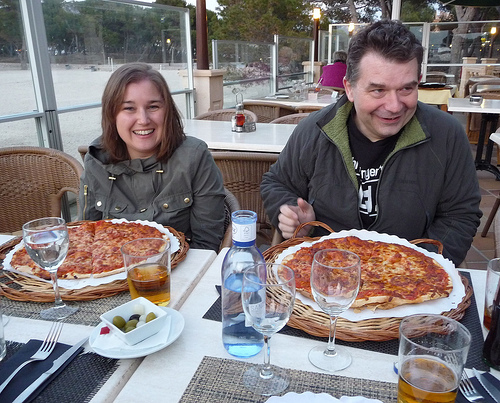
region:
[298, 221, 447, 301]
large pizza in basket tray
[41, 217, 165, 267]
large pizza in basket tray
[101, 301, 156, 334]
olives in square tray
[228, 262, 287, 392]
clear water glass on table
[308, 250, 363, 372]
clear water glass on table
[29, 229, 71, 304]
clear water glass on table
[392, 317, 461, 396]
glass of beer on table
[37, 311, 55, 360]
fork on placemat on table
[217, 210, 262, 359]
bottle of water on table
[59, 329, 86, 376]
knife laying on table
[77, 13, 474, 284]
coouple sitting at table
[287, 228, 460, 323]
pizza on white plate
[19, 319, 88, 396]
silver utensils on table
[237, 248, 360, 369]
two empty wine glasses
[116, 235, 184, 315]
glass half full of beer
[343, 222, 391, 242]
edge of white plate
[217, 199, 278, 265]
bottle neck with no cap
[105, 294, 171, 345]
olives in white dish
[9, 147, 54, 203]
back of wicker chair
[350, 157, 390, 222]
white design on black shirt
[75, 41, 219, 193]
girl looking at the camera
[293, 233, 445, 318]
pizza under the man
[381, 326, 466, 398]
glass on the table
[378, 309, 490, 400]
half full glass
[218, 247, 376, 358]
two wine glasses on the table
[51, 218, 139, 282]
pizza in front of woman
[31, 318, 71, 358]
fork on the table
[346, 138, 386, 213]
black and white shirt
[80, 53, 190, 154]
brown hair on girl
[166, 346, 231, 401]
placemat on table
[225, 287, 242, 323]
part of a bottle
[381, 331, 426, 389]
part of a glass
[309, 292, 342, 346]
part of a stand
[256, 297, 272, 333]
part of a glass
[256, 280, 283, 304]
edge of a glas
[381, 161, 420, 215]
part of a jumper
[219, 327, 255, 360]
part of a bottle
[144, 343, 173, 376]
part of a table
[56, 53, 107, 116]
Snow on ground outside building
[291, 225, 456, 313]
Pizza on a white doily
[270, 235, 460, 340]
Pizza presented on a basket dish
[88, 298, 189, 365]
Bowl of olives on table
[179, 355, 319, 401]
Light brown placemat on table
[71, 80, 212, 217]
Smiling girl in grey jacket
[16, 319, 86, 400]
Silver fork and knife on table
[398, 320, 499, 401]
Glass of beer next to silverware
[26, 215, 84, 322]
Glass of water on table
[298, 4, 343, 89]
Lamp post behind person in purple jacket